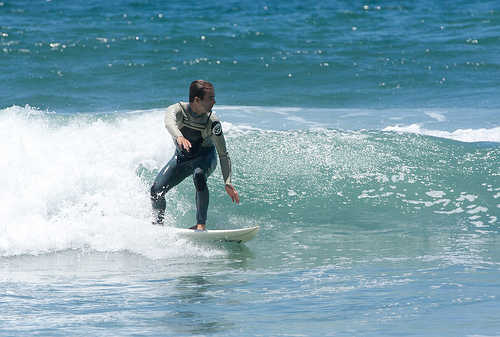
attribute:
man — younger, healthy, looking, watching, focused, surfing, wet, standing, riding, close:
[141, 63, 256, 210]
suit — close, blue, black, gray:
[169, 115, 231, 193]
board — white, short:
[225, 215, 261, 248]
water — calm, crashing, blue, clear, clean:
[289, 44, 419, 212]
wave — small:
[22, 104, 483, 236]